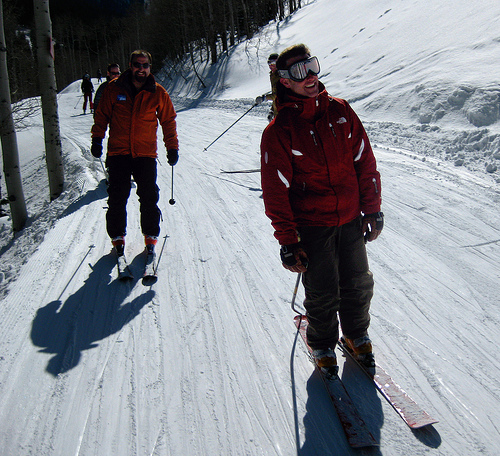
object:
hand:
[89, 146, 102, 157]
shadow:
[292, 359, 383, 456]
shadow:
[173, 46, 236, 111]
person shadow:
[30, 248, 157, 378]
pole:
[171, 164, 174, 200]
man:
[259, 42, 384, 373]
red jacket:
[260, 81, 382, 246]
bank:
[409, 80, 500, 129]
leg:
[299, 239, 340, 349]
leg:
[339, 241, 374, 340]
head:
[129, 51, 154, 81]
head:
[276, 44, 320, 98]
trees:
[0, 0, 62, 234]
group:
[81, 43, 384, 374]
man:
[91, 49, 180, 255]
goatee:
[131, 74, 148, 83]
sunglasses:
[131, 61, 150, 69]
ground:
[0, 0, 500, 456]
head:
[106, 63, 122, 80]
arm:
[350, 117, 381, 214]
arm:
[261, 137, 298, 244]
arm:
[155, 97, 180, 149]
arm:
[91, 91, 112, 139]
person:
[81, 73, 94, 113]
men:
[91, 49, 178, 253]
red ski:
[317, 368, 379, 452]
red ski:
[356, 359, 440, 430]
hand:
[362, 211, 384, 242]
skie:
[295, 83, 304, 93]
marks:
[157, 327, 278, 451]